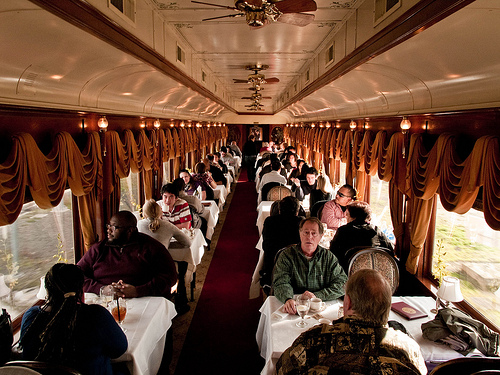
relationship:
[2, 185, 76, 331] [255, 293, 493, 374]
window next to table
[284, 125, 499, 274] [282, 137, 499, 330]
curtains on windows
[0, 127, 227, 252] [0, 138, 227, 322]
curtains on windows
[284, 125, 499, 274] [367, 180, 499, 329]
curtains above windows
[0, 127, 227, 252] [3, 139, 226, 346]
curtains above windows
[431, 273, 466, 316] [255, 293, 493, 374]
lamp on table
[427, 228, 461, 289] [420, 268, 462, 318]
flower in vase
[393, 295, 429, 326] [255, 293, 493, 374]
book on table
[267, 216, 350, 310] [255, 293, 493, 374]
man at table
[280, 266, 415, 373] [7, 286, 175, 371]
man sitting at dinning table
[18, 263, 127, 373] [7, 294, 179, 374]
woman sitting at dinning table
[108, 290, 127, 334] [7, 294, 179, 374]
glass on dinning table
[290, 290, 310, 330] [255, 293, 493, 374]
glass on table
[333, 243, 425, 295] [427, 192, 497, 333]
chair next to window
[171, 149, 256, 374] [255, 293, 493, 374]
aisle down middle of table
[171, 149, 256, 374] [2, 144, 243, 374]
aisle down middle of tables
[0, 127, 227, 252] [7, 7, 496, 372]
curtains down left side of train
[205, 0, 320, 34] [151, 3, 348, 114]
fan in center